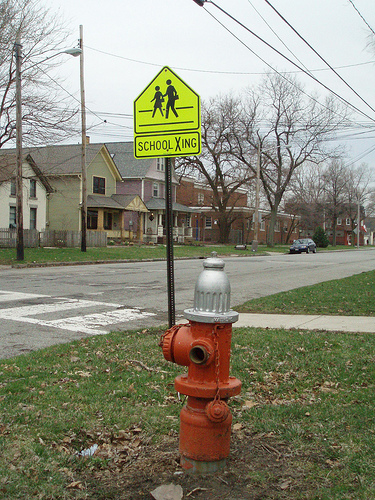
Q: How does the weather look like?
A: Cloudy.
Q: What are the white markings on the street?
A: A crosswalk.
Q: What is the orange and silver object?
A: A fire hydrant.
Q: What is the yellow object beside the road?
A: A crossing sign.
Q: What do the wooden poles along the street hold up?
A: Electrical wires.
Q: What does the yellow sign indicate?
A: School crossing.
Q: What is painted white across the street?
A: Crosswalk.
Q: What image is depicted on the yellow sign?
A: Pedestrians crossing street.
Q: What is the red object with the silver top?
A: Fire hydrant.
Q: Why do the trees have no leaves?
A: Season is Fall.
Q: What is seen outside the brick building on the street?
A: Car.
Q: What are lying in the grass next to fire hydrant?
A: Leaves.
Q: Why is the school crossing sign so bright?
A: To draw attention.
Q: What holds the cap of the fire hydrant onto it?
A: Chain.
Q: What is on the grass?
A: Red fire hydrant.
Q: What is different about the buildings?
A: The colors.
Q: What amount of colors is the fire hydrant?
A: Two.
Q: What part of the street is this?
A: Crosswalk.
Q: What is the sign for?
A: School crossing.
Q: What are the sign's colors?
A: Yellow and black.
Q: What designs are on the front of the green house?
A: Sun rays.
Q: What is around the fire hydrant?
A: Dirt.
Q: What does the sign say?
A: School Xing.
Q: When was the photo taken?
A: Daytime.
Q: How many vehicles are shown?
A: One.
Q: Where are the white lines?
A: Street.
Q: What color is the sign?
A: Yellow.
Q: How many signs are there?
A: One.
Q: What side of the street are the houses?
A: Left.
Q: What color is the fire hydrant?
A: Red and gray.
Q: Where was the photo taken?
A: On the street.